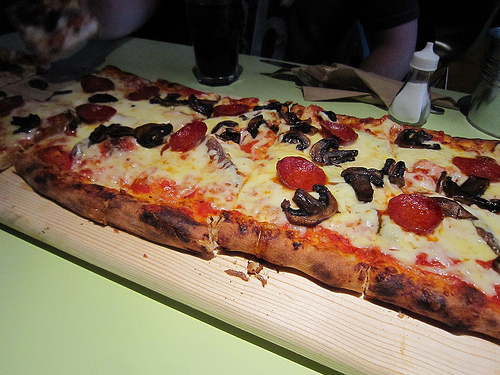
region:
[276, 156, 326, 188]
a curled piece of pepperoni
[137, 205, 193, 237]
charred area on pizza crust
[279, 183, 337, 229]
mushroom slice on a pizza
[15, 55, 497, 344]
a large oblong pizza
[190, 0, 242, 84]
a glass with a dark beverage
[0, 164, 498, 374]
a blond piece of wood under the pizza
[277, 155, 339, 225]
pepperoni and mushroom as toppings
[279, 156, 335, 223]
pepperoni and mushroom on a pizza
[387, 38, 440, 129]
a container of sugar on the table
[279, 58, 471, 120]
brown paper napkins behind the pizza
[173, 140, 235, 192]
cheese on a pizza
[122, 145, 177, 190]
cheese on a pizza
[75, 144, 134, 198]
cheese on a pizza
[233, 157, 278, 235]
cheese on a pizza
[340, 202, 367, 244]
cheese on a pizza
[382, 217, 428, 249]
cheese on a pizza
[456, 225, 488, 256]
cheese on a pizza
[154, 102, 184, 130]
cheese on a pizza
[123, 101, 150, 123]
cheese on a pizza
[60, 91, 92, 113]
cheese on a pizza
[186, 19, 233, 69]
Brown liquid in glass.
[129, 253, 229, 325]
Brown board on table.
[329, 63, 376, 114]
Brown napkin on table.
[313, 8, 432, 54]
Person wearing t-shirt.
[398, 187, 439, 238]
Red pepperoni on pizza.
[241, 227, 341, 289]
Golden brown crust on pizza.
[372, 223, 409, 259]
White cheese melted on pizza.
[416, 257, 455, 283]
Red sauce on pizza.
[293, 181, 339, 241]
Piece of mushroom on pizza.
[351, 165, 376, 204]
Piece of mushroom on pizza.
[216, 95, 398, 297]
a slice of pizza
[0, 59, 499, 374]
the cutting board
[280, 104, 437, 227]
mushrooms on a slice pizza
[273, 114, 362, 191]
pepperoni on a slice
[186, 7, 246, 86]
a cup on table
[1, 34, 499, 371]
the table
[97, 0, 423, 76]
a person to right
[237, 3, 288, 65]
logo on the shirt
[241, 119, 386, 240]
cheese in a bottle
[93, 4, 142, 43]
elbow on table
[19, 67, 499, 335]
mushrooms pizza on a table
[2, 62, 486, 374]
brown wooden table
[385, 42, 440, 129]
salt shaker on a table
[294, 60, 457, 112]
brown napkin on green table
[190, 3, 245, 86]
black soda cup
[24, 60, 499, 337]
sliced pizza on a table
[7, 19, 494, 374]
green tablecloth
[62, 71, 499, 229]
sliced pepperoni on a pizza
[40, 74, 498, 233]
sliced mushrooms on a pizza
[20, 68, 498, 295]
melted cheese on a pizza